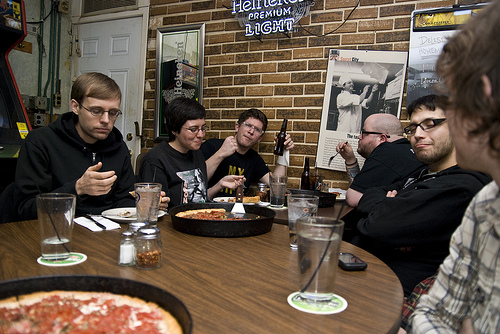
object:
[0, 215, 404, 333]
table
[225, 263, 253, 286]
wood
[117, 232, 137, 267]
salt shaker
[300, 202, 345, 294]
straw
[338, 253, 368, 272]
cellphone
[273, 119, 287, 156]
beer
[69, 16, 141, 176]
door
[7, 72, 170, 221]
man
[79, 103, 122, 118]
eyeglasses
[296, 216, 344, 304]
glass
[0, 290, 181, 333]
pizza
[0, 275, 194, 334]
pan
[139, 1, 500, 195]
wall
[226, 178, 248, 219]
spatula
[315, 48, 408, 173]
poster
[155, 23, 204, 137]
mirror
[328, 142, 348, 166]
fork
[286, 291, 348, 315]
coaster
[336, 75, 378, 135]
man